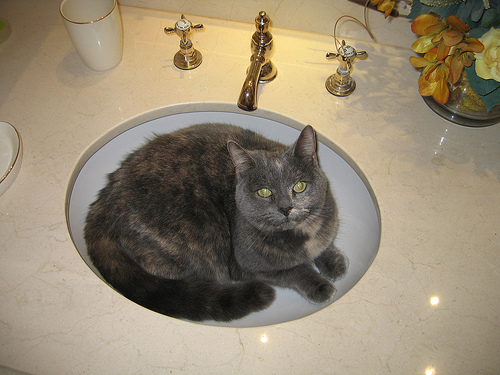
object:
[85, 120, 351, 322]
cat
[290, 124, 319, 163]
ear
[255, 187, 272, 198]
eye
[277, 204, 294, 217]
nose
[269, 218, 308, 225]
mouth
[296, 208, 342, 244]
whiskers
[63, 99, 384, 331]
sink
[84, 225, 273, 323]
tail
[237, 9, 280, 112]
faucet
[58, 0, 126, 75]
glass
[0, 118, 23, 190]
dish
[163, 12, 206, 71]
handle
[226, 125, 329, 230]
head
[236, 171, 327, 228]
face